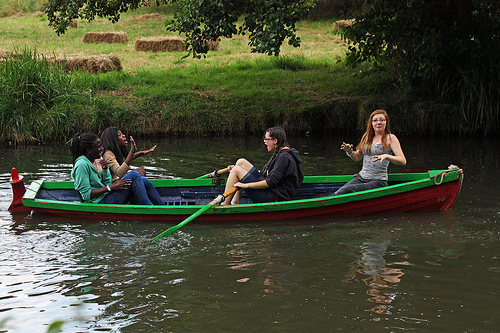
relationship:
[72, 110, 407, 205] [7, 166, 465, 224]
women in a row boat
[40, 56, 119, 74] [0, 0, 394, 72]
haystack in field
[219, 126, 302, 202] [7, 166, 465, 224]
woman sitting in row boat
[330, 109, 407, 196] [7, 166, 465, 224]
women on row boat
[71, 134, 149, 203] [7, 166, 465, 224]
woman on row boat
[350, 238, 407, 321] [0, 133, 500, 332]
woman's reflection in water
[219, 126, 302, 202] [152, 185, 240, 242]
woman holding oar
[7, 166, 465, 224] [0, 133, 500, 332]
row boat in water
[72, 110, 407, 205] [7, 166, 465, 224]
women are in row boat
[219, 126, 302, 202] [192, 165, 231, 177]
woman holding an oar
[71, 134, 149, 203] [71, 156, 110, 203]
woman wearing sweatshirt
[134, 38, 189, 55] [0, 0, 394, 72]
bale of hay in field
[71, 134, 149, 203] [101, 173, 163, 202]
woman wearing jeans